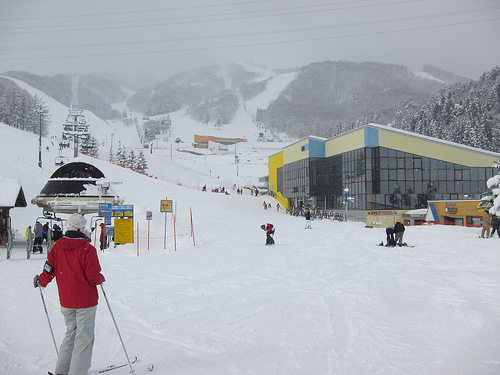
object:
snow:
[0, 0, 500, 375]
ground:
[0, 200, 499, 375]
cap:
[63, 212, 88, 230]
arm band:
[42, 263, 54, 273]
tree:
[408, 71, 500, 140]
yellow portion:
[264, 154, 294, 204]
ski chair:
[52, 90, 97, 165]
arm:
[39, 239, 61, 290]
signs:
[99, 199, 136, 245]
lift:
[45, 95, 111, 261]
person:
[34, 212, 102, 375]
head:
[64, 212, 89, 233]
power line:
[0, 0, 500, 43]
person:
[260, 222, 278, 246]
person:
[33, 220, 44, 255]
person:
[392, 220, 406, 246]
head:
[396, 221, 400, 223]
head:
[484, 208, 489, 215]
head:
[260, 224, 267, 231]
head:
[36, 218, 41, 223]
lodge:
[313, 122, 500, 228]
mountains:
[0, 21, 500, 159]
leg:
[55, 306, 80, 375]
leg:
[72, 310, 96, 374]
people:
[252, 216, 408, 251]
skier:
[305, 210, 312, 230]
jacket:
[305, 212, 312, 220]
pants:
[305, 220, 312, 229]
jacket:
[38, 238, 105, 309]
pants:
[54, 302, 97, 373]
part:
[80, 319, 95, 342]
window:
[273, 146, 496, 215]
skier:
[386, 225, 395, 247]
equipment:
[375, 240, 416, 248]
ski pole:
[96, 272, 138, 375]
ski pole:
[33, 277, 65, 364]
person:
[480, 208, 491, 238]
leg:
[481, 225, 490, 236]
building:
[268, 120, 500, 226]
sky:
[1, 0, 499, 90]